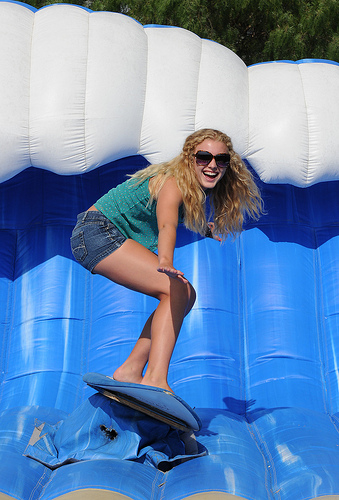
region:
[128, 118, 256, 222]
woman with long blonde wavy hair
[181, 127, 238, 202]
woman wearing large dark sunglasses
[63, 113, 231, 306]
woman wearing blue denim shorts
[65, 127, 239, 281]
woman wearing teal colored tank top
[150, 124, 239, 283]
woman balancing with arms outstretched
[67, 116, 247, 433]
woman balancing on blue surfboard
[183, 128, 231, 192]
sunlit smiling Caucasian woman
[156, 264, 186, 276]
four Caucasian fingers pointing outward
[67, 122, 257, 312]
woman crouched in front of blue and white inflatable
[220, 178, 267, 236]
loose long blonde hair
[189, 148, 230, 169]
large dark black sunglasses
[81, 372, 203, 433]
a blue and white surfboard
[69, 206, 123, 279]
a woman's blue jean shorts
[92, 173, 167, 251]
part of a woman's green shirt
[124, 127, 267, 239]
a woman's curly blonde hair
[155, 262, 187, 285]
the hand of a woman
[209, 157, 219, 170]
the nose of a man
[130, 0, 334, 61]
green tree leaves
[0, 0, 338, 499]
a large blue and white inflatable jumper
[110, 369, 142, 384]
part of a girl's barefoot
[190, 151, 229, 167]
sunglasses on the girl's face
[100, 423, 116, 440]
a rip in the tarp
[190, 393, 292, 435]
woman's shadow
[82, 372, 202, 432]
fake surfboard platform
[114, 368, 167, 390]
bare feet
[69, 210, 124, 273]
she is wearing blue jean shorts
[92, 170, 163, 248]
a green tank top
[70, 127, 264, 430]
the girl is posing on a fake surfboard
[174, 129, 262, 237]
curly blonde hair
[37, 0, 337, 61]
green trees in the background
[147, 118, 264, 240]
long wavey blond hair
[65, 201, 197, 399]
legs with short shorts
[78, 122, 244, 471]
woman wearing sunglasses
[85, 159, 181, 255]
a green sleeveless top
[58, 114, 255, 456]
woman crouched on surfboard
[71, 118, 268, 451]
woman surfing on inflatable waves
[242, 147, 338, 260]
a dark blue stripe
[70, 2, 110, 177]
seam in white material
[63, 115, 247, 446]
woman with arm extended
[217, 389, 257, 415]
shadow that looks like a bird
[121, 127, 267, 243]
A woman with long blond hair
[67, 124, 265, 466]
A woman riding a surfing simulator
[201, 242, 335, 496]
Giant blue inflatable pads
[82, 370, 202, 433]
Soft blue covered surfboard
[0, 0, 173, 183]
Large white inflatable pads made to look like a wave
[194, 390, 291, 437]
Shadow of the woman on the blue pads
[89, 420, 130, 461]
A tear in the blue canvas covering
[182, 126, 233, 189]
A woman wearing large sunglasses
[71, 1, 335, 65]
Large green trees in the distance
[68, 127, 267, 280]
A woman wearing jean shorts and a green shirt